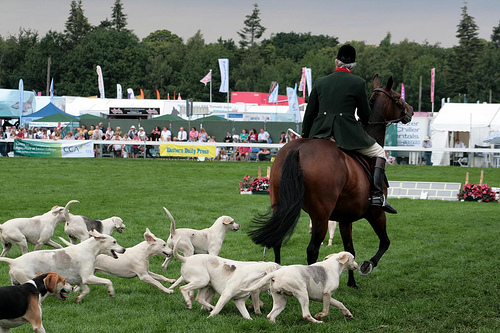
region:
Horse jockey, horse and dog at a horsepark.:
[7, 5, 486, 324]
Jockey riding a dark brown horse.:
[242, 51, 436, 263]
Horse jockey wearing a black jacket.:
[297, 37, 419, 142]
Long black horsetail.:
[222, 138, 338, 253]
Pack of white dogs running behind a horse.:
[7, 185, 386, 315]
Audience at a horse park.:
[4, 105, 495, 173]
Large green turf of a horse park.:
[8, 162, 498, 329]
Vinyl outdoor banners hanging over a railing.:
[12, 137, 244, 171]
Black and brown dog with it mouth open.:
[7, 270, 77, 330]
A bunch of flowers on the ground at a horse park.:
[450, 152, 495, 212]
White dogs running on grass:
[103, 208, 251, 328]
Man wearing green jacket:
[297, 45, 372, 145]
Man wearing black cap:
[297, 37, 367, 151]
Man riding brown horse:
[258, 42, 419, 250]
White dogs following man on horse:
[56, 54, 413, 321]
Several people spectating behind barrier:
[27, 121, 209, 169]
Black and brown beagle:
[1, 272, 83, 329]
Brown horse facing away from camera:
[374, 72, 426, 132]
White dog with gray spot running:
[268, 250, 361, 322]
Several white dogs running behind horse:
[71, 169, 373, 323]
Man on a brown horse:
[257, 43, 397, 290]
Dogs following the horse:
[3, 204, 375, 328]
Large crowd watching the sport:
[0, 116, 302, 161]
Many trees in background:
[0, 15, 498, 97]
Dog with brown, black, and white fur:
[0, 272, 75, 332]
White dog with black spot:
[64, 195, 128, 241]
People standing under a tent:
[1, 86, 274, 153]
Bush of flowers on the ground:
[453, 180, 499, 217]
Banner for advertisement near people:
[156, 141, 224, 163]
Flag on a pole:
[197, 69, 216, 101]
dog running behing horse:
[0, 271, 78, 331]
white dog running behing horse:
[64, 197, 128, 244]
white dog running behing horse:
[0, 200, 65, 250]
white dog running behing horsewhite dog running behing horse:
[0, 227, 125, 302]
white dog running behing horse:
[92, 228, 179, 292]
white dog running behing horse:
[160, 202, 240, 272]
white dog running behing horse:
[171, 234, 281, 323]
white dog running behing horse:
[239, 250, 360, 323]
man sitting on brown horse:
[300, 42, 399, 216]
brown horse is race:
[246, 71, 414, 291]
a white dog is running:
[10, 231, 122, 315]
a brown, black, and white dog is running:
[0, 270, 75, 332]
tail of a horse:
[250, 148, 304, 246]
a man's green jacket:
[293, 73, 378, 149]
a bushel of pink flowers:
[455, 182, 494, 202]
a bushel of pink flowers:
[237, 172, 267, 196]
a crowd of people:
[2, 122, 277, 145]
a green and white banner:
[10, 137, 92, 162]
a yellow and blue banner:
[157, 141, 218, 158]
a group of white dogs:
[1, 204, 361, 326]